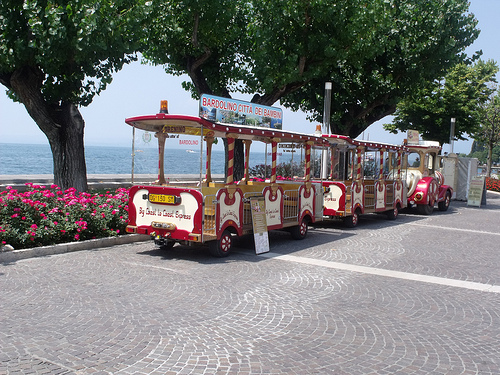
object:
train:
[128, 99, 323, 248]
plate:
[148, 195, 178, 204]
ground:
[59, 283, 148, 319]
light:
[159, 100, 169, 114]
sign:
[198, 91, 286, 133]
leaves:
[76, 47, 90, 51]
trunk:
[28, 101, 93, 196]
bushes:
[0, 205, 46, 231]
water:
[109, 158, 131, 168]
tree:
[17, 0, 95, 188]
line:
[320, 259, 363, 270]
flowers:
[6, 186, 18, 197]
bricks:
[40, 286, 57, 300]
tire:
[220, 226, 242, 258]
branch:
[73, 82, 104, 101]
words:
[198, 95, 209, 104]